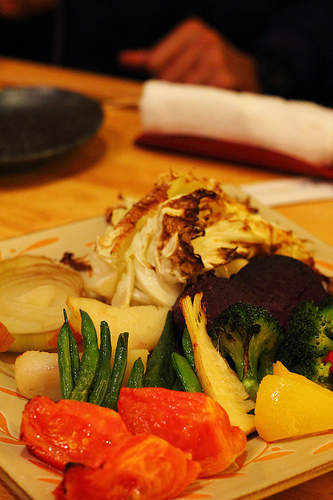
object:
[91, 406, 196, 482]
tomatoes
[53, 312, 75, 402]
beans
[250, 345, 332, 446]
lemon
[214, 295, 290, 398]
broccoli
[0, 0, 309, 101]
man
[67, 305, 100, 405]
snow pea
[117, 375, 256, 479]
vegetables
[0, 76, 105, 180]
pan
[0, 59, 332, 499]
table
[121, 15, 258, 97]
hand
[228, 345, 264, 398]
stalks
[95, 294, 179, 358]
pineapple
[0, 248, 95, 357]
onions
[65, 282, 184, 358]
potatoes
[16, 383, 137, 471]
food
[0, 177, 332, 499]
dish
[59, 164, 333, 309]
veggies